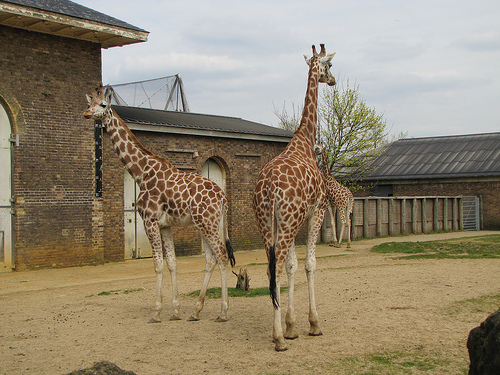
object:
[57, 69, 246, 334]
giraffe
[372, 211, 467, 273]
grass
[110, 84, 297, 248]
building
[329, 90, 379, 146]
tree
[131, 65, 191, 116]
fence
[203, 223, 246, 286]
tail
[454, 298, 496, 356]
rock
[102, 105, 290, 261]
house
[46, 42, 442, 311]
background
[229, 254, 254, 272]
tip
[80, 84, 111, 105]
horn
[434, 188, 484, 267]
gate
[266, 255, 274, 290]
hair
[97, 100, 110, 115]
eye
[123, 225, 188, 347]
leg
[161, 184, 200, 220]
spot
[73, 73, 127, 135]
head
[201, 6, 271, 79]
day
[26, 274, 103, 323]
ground